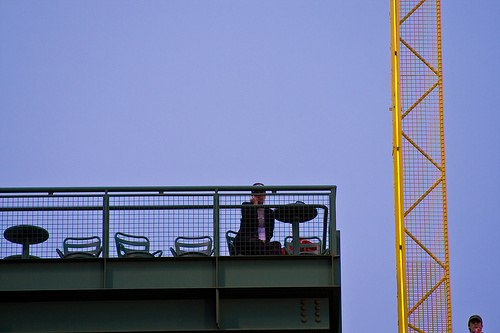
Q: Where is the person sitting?
A: On a chair.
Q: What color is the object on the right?
A: Yellow.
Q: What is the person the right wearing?
A: A hat.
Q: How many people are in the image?
A: Two.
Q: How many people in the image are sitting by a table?
A: One.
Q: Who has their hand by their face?
A: Person by table.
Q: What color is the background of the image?
A: Blue.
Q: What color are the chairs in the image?
A: Green.